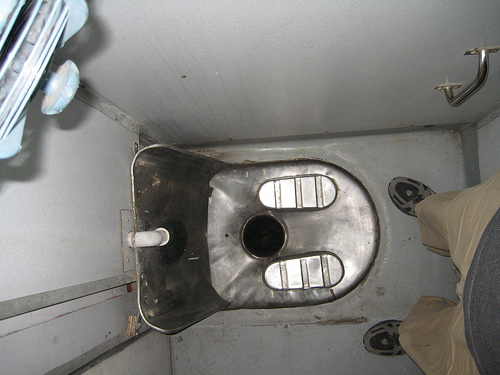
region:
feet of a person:
[367, 151, 438, 246]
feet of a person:
[363, 288, 427, 373]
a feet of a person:
[366, 166, 444, 233]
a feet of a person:
[346, 298, 421, 365]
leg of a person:
[410, 171, 495, 263]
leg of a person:
[395, 291, 469, 371]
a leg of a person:
[419, 181, 490, 263]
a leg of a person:
[402, 293, 472, 363]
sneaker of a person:
[365, 165, 450, 216]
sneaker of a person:
[357, 296, 409, 370]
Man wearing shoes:
[357, 168, 453, 361]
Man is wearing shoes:
[359, 172, 449, 362]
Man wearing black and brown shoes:
[355, 166, 445, 359]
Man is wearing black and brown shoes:
[351, 171, 450, 363]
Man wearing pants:
[394, 167, 498, 374]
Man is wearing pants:
[390, 163, 498, 373]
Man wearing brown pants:
[390, 167, 499, 373]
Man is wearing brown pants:
[394, 167, 498, 372]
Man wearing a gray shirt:
[446, 187, 498, 372]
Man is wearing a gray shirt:
[455, 195, 499, 374]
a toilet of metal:
[105, 134, 385, 333]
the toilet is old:
[117, 134, 382, 342]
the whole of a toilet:
[231, 204, 291, 266]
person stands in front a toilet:
[241, 145, 498, 372]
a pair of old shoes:
[367, 156, 439, 363]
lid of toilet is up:
[114, 132, 236, 338]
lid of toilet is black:
[116, 142, 218, 334]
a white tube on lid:
[121, 222, 172, 253]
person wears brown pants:
[364, 171, 498, 371]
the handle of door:
[434, 42, 495, 112]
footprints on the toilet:
[245, 162, 350, 302]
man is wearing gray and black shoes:
[341, 154, 439, 372]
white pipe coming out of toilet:
[120, 217, 185, 262]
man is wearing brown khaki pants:
[404, 162, 499, 367]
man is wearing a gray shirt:
[452, 193, 497, 373]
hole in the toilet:
[231, 205, 300, 272]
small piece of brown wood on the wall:
[120, 291, 165, 353]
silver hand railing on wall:
[449, 44, 494, 143]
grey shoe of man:
[386, 173, 431, 216]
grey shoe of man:
[362, 319, 404, 359]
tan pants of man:
[397, 176, 498, 373]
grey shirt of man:
[464, 202, 498, 367]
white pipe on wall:
[124, 227, 169, 246]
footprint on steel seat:
[262, 244, 344, 296]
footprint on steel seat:
[255, 172, 335, 207]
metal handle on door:
[444, 50, 497, 110]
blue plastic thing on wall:
[0, 1, 97, 171]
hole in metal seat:
[240, 213, 289, 258]